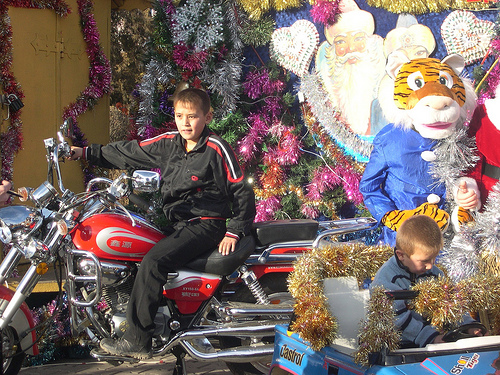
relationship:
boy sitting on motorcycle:
[61, 82, 261, 365] [3, 108, 382, 373]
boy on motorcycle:
[64, 86, 256, 359] [3, 108, 382, 373]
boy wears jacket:
[64, 86, 256, 359] [83, 130, 256, 239]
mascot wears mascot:
[358, 56, 479, 250] [358, 56, 479, 250]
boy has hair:
[368, 215, 483, 345] [395, 215, 440, 248]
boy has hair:
[64, 86, 256, 359] [175, 87, 211, 108]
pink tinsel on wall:
[58, 2, 113, 192] [11, 0, 112, 196]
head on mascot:
[381, 48, 473, 140] [358, 56, 479, 250]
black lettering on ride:
[277, 344, 303, 366] [277, 274, 444, 371]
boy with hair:
[368, 215, 483, 347] [386, 215, 442, 262]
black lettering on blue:
[264, 334, 316, 374] [263, 322, 319, 365]